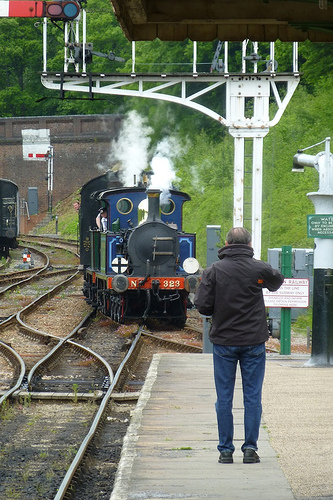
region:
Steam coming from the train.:
[100, 112, 182, 187]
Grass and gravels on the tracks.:
[10, 285, 88, 364]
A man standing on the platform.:
[191, 219, 285, 444]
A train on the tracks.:
[69, 160, 192, 335]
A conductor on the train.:
[89, 207, 114, 231]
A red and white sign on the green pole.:
[244, 272, 321, 315]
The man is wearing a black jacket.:
[195, 258, 285, 347]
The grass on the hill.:
[174, 100, 307, 238]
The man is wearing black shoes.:
[220, 441, 290, 476]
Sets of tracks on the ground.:
[7, 267, 96, 423]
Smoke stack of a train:
[144, 187, 164, 224]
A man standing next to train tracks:
[195, 225, 281, 464]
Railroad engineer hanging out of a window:
[97, 200, 110, 234]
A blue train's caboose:
[84, 186, 197, 319]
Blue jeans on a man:
[210, 326, 265, 454]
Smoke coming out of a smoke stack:
[148, 153, 174, 189]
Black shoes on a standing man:
[216, 444, 262, 466]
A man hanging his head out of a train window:
[71, 196, 84, 215]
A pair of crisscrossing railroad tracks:
[1, 319, 113, 407]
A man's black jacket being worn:
[192, 243, 283, 347]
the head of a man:
[212, 219, 262, 260]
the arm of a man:
[191, 258, 235, 313]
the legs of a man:
[210, 339, 281, 466]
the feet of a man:
[208, 440, 275, 474]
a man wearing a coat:
[194, 227, 283, 345]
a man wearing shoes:
[210, 429, 293, 471]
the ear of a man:
[214, 236, 243, 252]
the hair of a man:
[217, 209, 262, 256]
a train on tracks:
[56, 163, 237, 346]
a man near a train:
[76, 212, 307, 415]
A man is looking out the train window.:
[63, 161, 202, 332]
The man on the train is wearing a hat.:
[72, 166, 203, 336]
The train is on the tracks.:
[38, 155, 231, 368]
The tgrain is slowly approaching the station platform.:
[56, 140, 329, 361]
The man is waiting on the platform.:
[139, 219, 332, 483]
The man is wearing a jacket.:
[186, 219, 292, 482]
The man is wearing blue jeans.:
[187, 223, 286, 470]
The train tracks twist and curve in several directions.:
[2, 230, 283, 499]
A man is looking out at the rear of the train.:
[63, 160, 204, 330]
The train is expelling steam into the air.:
[74, 106, 205, 337]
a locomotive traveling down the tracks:
[37, 149, 203, 337]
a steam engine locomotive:
[63, 167, 207, 342]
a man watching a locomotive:
[130, 171, 283, 463]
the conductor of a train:
[97, 206, 112, 236]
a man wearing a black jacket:
[190, 218, 291, 352]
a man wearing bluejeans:
[199, 222, 284, 465]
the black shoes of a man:
[215, 443, 261, 469]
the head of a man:
[224, 226, 253, 249]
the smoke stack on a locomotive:
[144, 187, 163, 224]